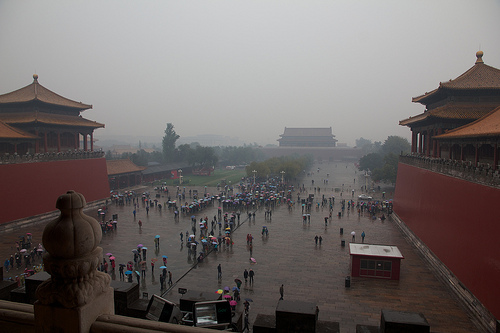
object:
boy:
[278, 284, 285, 299]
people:
[0, 159, 393, 333]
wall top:
[0, 149, 107, 164]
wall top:
[398, 151, 500, 189]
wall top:
[35, 190, 113, 333]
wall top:
[279, 147, 347, 150]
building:
[348, 243, 405, 280]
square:
[392, 162, 500, 320]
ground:
[441, 104, 476, 154]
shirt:
[280, 287, 284, 294]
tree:
[162, 122, 181, 157]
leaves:
[358, 134, 411, 183]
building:
[398, 42, 500, 187]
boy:
[154, 235, 161, 253]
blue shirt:
[154, 239, 158, 244]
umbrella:
[154, 235, 160, 238]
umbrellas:
[251, 258, 257, 263]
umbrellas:
[348, 229, 360, 237]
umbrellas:
[109, 256, 116, 260]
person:
[244, 269, 255, 284]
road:
[0, 161, 500, 333]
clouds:
[0, 0, 500, 149]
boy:
[128, 171, 168, 201]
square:
[0, 158, 110, 222]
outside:
[0, 0, 500, 333]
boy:
[119, 264, 124, 278]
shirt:
[127, 263, 132, 270]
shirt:
[148, 193, 150, 196]